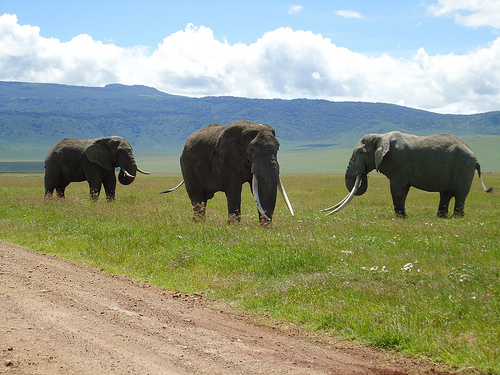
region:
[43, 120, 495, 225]
Three elephants walking on the ground.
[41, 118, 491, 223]
Three elephants walking in wildlife park.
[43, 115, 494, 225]
Three elephants with ivory horns.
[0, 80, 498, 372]
Wildlife park with three elephants.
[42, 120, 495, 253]
Brown and gray elephants walking on green grass.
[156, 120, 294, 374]
Elephant walking near a dirt road.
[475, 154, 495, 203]
Tail of a gray elephant.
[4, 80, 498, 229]
Mountain behind the elephants walking on the grass.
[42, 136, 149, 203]
Elephant walking behind another elephant.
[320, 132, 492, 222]
Gray elephant walking towards the elephant behind another elephant.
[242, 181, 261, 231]
ivory tusk on elephant.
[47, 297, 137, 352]
brown dirt on path.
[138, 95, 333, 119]
hills in the background.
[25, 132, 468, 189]
three elephants in the field.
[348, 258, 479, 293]
small flowers in the grass.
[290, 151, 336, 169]
green grass in the distance.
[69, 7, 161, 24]
clear blue sky above the hills.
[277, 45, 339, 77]
large white clouds in the sky.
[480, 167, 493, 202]
curly elephant tail.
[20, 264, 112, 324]
small pebbles in the dirt.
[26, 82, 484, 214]
three elephants with horns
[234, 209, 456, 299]
grass with flowers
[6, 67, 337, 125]
mountains on the top of the hills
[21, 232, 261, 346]
muddy road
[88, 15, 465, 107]
cloudy sky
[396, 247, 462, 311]
white flower on the grass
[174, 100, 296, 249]
big elephant with two horns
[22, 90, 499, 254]
elephants standing in the grass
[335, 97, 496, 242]
elephant moving his tail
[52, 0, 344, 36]
blue sky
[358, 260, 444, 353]
The grass is light green and there are white flowers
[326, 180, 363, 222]
The tusks of the elephant are bright white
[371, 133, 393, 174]
The elephant's ear is large and can flap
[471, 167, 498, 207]
The elephant's tail plays a critical role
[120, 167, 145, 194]
The elephant's trunk is grey and helps in eating and drinking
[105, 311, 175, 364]
The gravel is light brown and looks dry in texture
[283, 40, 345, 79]
The clouds are white and puffy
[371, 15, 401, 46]
The sky is a light blue color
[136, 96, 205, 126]
The mountain is dark green with vegetation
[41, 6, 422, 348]
The scene of this photo is from Africa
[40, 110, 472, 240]
three large elephants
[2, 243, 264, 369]
dirt road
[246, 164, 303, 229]
long white tusks of an elephant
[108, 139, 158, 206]
short white elephant tusks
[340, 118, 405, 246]
an elephant eating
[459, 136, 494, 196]
the tail of an elephant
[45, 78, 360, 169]
green hill side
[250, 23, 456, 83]
soft white clouds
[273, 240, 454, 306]
long green grass and flowers in a field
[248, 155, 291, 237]
a long grey elephant trunk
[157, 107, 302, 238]
grey elephant with white tusks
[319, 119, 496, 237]
elephant with long white tusks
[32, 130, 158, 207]
elephant with two white tusks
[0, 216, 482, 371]
well-maintianed brown dirt road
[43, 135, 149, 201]
Ann elephant with its trunk curled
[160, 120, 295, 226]
African elephant with large tusks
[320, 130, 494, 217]
Elephant eating in an African grassland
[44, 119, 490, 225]
A group of three elephants standing together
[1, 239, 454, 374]
Brown dry dirt road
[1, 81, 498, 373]
African grassland with hills in the distance